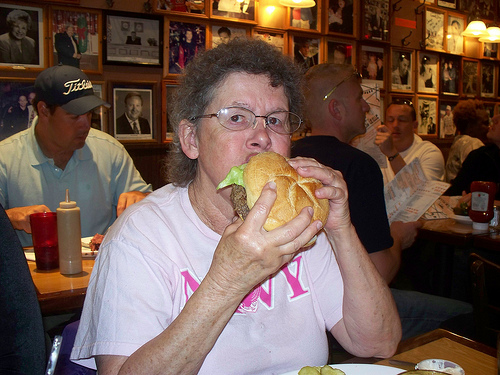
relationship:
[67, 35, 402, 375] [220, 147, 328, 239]
people eating a burger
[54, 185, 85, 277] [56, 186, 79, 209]
bottle has lid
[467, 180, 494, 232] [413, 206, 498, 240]
ketchup bottle on top of table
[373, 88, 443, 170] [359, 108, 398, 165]
man looking a menu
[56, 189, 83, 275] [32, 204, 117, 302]
bottle on top of table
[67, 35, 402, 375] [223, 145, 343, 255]
people eating hamburger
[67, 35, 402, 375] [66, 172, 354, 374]
people wearing shirt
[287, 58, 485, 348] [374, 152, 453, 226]
man reading a menu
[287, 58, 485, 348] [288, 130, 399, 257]
man wearing black shirt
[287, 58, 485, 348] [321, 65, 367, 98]
man wearing sunglasses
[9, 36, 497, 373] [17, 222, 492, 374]
people seating at tables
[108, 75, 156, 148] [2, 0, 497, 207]
photograph are crowded onto a wall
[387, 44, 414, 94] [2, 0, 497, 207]
photograph are crowded onto a wall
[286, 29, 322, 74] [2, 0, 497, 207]
photograph are crowded onto a wall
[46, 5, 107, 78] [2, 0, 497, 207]
photograph are crowded onto a wall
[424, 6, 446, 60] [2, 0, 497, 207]
photograph are crowded onto a wall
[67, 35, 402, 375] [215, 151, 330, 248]
people eating burger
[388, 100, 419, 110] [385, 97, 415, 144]
glasses up high on mans head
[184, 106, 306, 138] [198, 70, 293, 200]
glasses on womans face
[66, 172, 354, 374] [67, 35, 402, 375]
shirt on people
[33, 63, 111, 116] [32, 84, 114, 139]
cap on mans head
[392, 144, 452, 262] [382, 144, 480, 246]
menu in mans hand